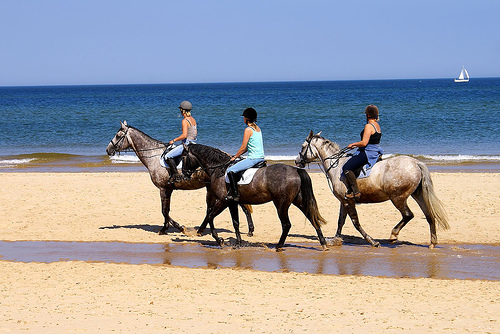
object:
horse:
[293, 129, 450, 250]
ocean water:
[0, 88, 500, 151]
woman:
[164, 100, 197, 182]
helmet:
[178, 99, 194, 111]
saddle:
[224, 155, 267, 185]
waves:
[430, 153, 498, 162]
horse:
[179, 140, 331, 254]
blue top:
[246, 126, 265, 159]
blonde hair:
[179, 109, 192, 115]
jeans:
[164, 138, 199, 160]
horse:
[105, 119, 255, 237]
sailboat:
[453, 64, 471, 82]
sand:
[0, 156, 134, 192]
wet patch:
[0, 228, 500, 290]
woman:
[226, 107, 266, 201]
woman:
[342, 104, 385, 200]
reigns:
[322, 144, 352, 173]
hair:
[245, 107, 258, 129]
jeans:
[224, 157, 265, 184]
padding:
[224, 155, 267, 185]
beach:
[50, 155, 146, 189]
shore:
[17, 162, 133, 183]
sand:
[6, 230, 484, 290]